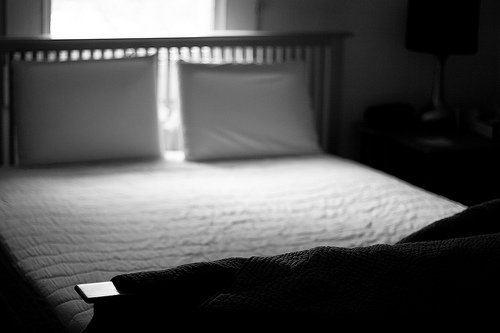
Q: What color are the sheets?
A: White.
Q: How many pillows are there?
A: Two.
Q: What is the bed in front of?
A: Window.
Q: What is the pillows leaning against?
A: Headboard.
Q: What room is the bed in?
A: Bedroom.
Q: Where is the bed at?
A: Middle of room.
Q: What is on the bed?
A: Blanket.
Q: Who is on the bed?
A: No one.